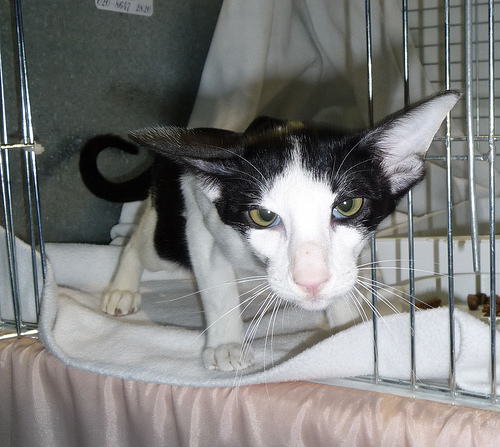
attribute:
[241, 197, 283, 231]
eye — cat's right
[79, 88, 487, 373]
cat — black and white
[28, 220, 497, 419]
blanket — white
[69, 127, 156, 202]
tail — black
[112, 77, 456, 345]
cat — black, white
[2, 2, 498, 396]
cage — metal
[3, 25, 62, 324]
cage — metal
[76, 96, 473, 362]
cat — standing up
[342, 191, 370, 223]
eye — cat's left